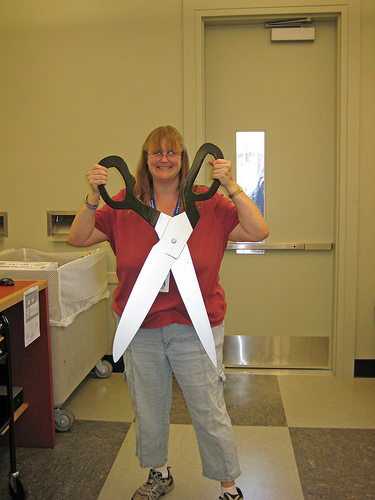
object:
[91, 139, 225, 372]
shears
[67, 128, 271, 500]
woman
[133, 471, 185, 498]
sneakers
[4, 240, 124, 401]
bin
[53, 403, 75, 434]
wheels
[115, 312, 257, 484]
pants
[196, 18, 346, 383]
door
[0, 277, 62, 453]
desk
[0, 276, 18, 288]
mouse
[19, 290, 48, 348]
paper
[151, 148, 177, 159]
glasses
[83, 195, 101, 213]
wristwatch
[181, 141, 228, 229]
handles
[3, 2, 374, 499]
room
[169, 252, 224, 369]
blade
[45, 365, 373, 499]
floor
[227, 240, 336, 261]
bar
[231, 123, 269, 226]
window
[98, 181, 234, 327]
shirt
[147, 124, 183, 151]
hair